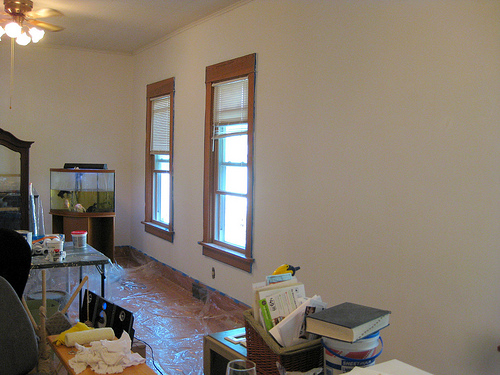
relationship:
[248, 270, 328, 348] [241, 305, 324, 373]
papers in basket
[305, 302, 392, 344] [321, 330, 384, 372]
black/hardback book on top of bucket